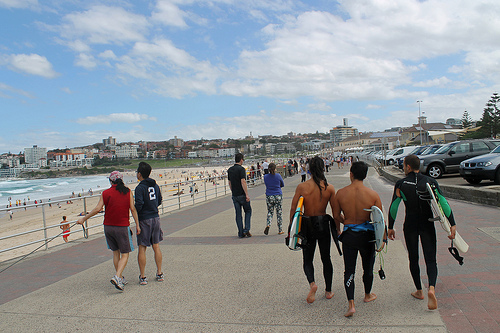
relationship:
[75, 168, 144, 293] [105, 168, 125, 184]
she wearing a hat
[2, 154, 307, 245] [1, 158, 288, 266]
people are in shore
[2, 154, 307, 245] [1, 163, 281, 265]
people are walking along beach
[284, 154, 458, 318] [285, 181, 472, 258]
they have surfboards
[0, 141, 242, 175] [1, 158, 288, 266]
buildings are along shore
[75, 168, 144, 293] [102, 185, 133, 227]
lady in red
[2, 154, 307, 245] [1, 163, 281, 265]
beachgoers are on beach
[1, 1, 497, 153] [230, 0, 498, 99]
sky has some clouds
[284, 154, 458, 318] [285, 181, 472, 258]
surfers are carrying their surfboards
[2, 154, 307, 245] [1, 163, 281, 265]
crowd hanging out on beach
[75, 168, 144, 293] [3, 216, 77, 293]
woman hanging onto rope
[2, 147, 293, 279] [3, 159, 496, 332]
fence dividing street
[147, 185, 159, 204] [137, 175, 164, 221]
number 2 on back of man's sweater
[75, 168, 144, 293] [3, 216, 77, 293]
lady holding leash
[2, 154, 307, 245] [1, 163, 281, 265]
people on beach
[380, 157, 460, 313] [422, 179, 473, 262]
guy carrying surfboard